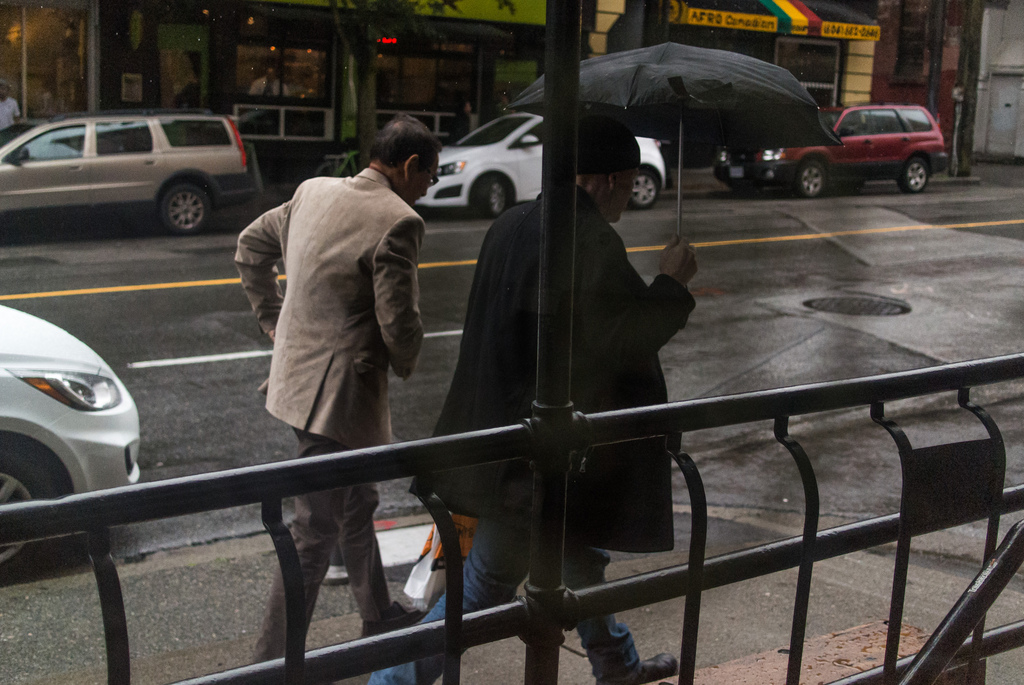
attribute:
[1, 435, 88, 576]
wheel — one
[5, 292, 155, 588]
vehicle — one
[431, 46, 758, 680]
person — one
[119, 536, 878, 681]
sidewalk — one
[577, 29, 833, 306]
umbrella — one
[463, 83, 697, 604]
man — one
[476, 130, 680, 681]
man — one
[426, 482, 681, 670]
jeans — blue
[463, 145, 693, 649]
man — one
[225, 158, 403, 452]
blazer — one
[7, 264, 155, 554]
car — one, white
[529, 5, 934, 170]
umbrella — black 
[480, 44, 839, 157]
umbrella — black, open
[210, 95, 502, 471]
man — dark haired, walking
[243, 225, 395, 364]
coat — brown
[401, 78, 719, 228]
car — white, parked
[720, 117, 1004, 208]
suv — red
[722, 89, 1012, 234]
suv — red, parked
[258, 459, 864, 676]
sidewalk — black, paved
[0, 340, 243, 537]
car — white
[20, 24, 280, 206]
suv — light gold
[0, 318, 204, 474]
car — parked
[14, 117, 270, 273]
car — parked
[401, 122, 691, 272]
car — parked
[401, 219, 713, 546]
jacket — black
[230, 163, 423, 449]
jacket — brown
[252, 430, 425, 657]
pants — brown